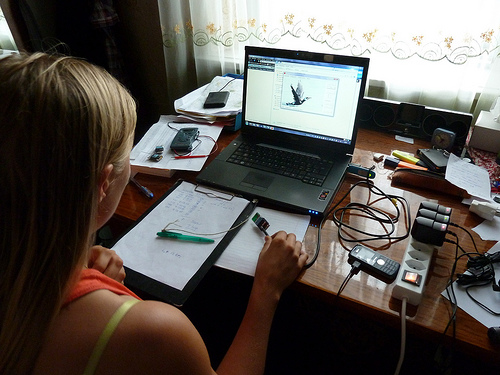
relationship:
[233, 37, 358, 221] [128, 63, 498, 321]
laptop on desk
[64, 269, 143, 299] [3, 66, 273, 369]
shirt of girl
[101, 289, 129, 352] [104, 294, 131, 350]
strap of bra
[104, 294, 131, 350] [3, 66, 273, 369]
bra of girl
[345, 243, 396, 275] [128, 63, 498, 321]
cellphone on desk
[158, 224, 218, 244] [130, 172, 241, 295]
pen on clip board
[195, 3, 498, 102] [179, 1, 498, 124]
curtain on window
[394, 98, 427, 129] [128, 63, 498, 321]
station on desk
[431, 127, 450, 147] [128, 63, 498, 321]
clock on desk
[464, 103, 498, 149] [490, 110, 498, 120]
box of tissues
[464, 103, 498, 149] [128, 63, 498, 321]
box on desk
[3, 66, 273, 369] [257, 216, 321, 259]
girl holding cord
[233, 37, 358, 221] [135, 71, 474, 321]
laptop on table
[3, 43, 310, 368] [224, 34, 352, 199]
girl looking at computer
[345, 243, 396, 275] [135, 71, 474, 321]
cellphone on table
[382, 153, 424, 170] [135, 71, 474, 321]
marker on table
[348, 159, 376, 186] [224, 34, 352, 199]
plug on computer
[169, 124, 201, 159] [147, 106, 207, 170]
recorder on paper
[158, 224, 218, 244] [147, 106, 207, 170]
pen on paper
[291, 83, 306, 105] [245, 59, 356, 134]
duck on screen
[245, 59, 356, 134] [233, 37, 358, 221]
screen of laptop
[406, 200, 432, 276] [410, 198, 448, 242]
plug with adapters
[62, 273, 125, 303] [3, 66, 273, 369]
top on girl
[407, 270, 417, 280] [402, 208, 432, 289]
light on outlet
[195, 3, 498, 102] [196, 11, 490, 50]
curtain with flowers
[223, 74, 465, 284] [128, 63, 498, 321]
electronics on desk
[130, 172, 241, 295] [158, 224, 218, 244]
clip board and pen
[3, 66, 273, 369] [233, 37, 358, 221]
girl on laptop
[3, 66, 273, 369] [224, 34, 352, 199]
girl on computer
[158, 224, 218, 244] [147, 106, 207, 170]
pen and paper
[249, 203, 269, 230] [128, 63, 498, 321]
charger on desk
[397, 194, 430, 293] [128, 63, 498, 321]
powerstrip on desk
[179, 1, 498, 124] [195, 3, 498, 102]
window with curtain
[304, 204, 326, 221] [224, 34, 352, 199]
lights on computer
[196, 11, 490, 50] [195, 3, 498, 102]
flowers on curtain